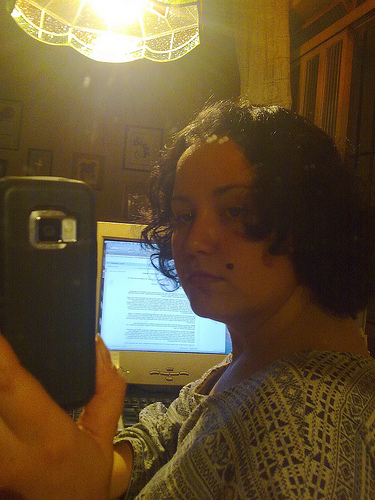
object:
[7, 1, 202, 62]
light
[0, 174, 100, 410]
mobile device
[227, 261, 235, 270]
mole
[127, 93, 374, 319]
black hair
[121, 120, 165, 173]
picture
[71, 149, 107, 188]
picture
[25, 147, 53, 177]
picture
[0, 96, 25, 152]
picture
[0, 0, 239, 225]
wall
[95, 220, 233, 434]
computer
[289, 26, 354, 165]
wooden door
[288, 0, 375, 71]
frame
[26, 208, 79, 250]
camera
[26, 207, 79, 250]
flash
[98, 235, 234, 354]
computer screen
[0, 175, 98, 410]
cellphone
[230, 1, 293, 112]
curtain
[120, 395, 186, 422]
keyboard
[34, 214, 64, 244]
camera eye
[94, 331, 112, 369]
nail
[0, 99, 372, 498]
woman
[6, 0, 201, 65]
lamp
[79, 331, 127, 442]
thumb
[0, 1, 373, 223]
background